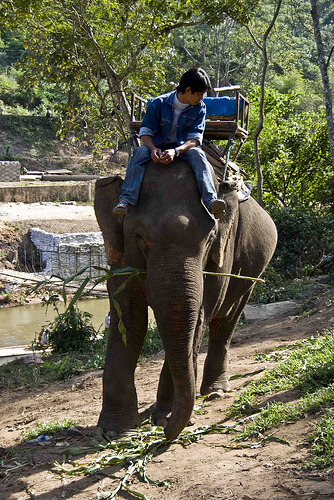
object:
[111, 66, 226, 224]
man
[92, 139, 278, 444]
elephant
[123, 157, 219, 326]
head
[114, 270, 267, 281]
stalk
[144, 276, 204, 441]
trunk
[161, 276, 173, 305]
grey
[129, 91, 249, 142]
blanket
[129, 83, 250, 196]
seat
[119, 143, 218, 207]
jeans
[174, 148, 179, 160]
watch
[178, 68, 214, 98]
hair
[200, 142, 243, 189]
back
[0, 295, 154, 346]
water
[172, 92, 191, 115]
turtleneck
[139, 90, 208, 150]
shirt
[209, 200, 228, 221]
shoes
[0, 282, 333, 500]
ground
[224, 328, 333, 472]
grass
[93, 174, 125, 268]
ear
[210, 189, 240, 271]
ear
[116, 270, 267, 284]
stick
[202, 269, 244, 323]
belly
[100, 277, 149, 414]
legs